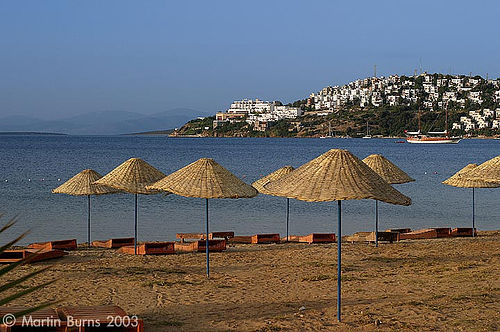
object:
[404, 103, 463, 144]
boat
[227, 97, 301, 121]
building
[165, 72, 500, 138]
island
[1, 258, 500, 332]
beach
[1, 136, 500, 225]
water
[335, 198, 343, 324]
pole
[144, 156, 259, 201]
sunbrella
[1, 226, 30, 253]
leaves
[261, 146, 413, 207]
umbrella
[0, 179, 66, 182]
rope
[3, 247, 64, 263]
chair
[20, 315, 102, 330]
letters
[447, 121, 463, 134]
buildings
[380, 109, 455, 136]
bushes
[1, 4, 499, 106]
sky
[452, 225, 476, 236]
chairs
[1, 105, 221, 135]
mountains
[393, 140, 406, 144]
people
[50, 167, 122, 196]
umbrellas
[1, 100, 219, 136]
distance